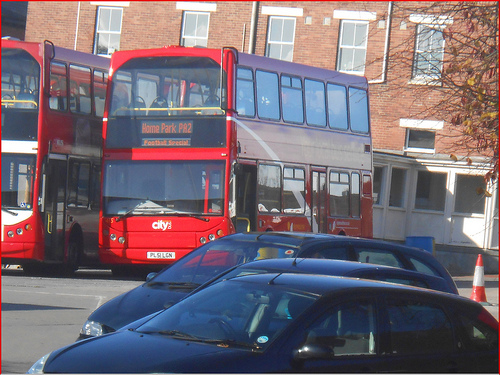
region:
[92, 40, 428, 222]
red bus parked in a lot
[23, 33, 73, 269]
red bus parked in a lot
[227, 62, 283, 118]
window on a bus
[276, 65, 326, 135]
window on a bus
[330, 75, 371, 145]
window on a bus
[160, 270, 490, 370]
car parked in a lot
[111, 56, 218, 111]
window on a bus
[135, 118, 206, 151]
sign on a bus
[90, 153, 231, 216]
window on a bus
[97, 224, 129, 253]
lights on a bus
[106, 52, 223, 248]
two story red bus parked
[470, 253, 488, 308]
red and white traffic cone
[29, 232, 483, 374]
three black cars of the same model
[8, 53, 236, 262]
red city bus parked by red bus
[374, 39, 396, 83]
white gutter pipe on red brick building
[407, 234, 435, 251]
blue trash can by red buses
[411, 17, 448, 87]
window with white trim on brick building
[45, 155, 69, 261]
black door on red bus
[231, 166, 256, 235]
open door on red bus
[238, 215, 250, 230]
yellow safety rail in red bus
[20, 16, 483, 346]
A bus is on a city street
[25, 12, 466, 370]
A bus is carrying passengers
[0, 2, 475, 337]
Two buses are running together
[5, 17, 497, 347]
A bus is bringing people home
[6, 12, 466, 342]
The bus has two levels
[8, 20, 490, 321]
The bus is on time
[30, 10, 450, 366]
The bus is running late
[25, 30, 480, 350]
The bus has come from the garage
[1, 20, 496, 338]
The bus is moving slowly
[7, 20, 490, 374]
The bus has just made a stop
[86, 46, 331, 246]
Red double decker bus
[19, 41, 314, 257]
two double decker buses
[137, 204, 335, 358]
two cars next to each other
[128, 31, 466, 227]
bus in front of a building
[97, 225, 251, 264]
head lights on a bus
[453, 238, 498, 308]
orange and white cone on the street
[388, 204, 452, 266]
blue bin on the sidewalk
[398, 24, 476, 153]
tree near the building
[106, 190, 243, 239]
windshield wiper on the bus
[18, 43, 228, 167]
two red buses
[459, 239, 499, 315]
safety cone in the street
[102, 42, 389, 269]
red double decker bus in the street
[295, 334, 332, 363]
sideview mirror on car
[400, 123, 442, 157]
window on a building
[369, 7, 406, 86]
pipe along side of building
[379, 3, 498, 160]
leaves on a bare tree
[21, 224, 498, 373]
cars in the street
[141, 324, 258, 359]
windshield wipers on a car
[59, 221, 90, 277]
tire on a bus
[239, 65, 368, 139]
side windows on a bus